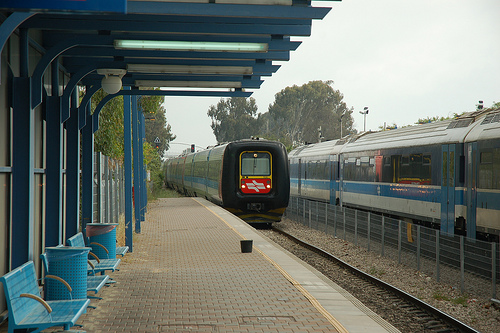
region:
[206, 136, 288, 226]
a silver train car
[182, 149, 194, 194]
a silver train car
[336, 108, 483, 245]
a white and blue train passenger car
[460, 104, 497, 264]
a white and blue train passenger car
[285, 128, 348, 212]
a white and blue train passenger car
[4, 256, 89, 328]
a light blue metal park bench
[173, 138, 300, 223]
train leaving the station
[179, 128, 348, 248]
train leaving the station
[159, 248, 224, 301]
brick on the sidewalk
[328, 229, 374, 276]
gravel between the tracks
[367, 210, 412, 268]
a fence between the trains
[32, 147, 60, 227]
a window in the building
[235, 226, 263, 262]
a bucket on the ground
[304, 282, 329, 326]
a yellow line on the ground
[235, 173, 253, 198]
lights on a train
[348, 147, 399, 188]
windows in a train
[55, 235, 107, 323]
a garbage can next to the building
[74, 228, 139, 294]
a bench next to the building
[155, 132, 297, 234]
train approaching a platform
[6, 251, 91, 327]
Blue park bench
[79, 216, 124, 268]
Blue metal garbage can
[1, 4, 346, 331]
Train platform with a blue overhang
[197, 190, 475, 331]
Standard width train track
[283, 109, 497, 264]
Freight train parked on a track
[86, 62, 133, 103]
Globe light on train platform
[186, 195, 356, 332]
Yellow caution line at train station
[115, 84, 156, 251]
Blue support poles at train station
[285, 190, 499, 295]
Metal fence separates trains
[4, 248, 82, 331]
A blue bench.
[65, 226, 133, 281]
A blue bench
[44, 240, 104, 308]
A blue trashcan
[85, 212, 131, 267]
A blue trashcan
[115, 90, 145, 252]
A blue pole next to the benches.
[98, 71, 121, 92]
A circular light above the benches.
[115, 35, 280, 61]
A long tube light illuminated.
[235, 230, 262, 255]
A black object on the platform.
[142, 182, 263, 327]
The train platform on the left.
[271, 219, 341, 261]
The train tracks in front the train.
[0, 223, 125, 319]
Blue garbage can next to bench.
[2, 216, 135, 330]
Blue benches with brown handles.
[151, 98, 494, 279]
Two trains on tracks next to each other.